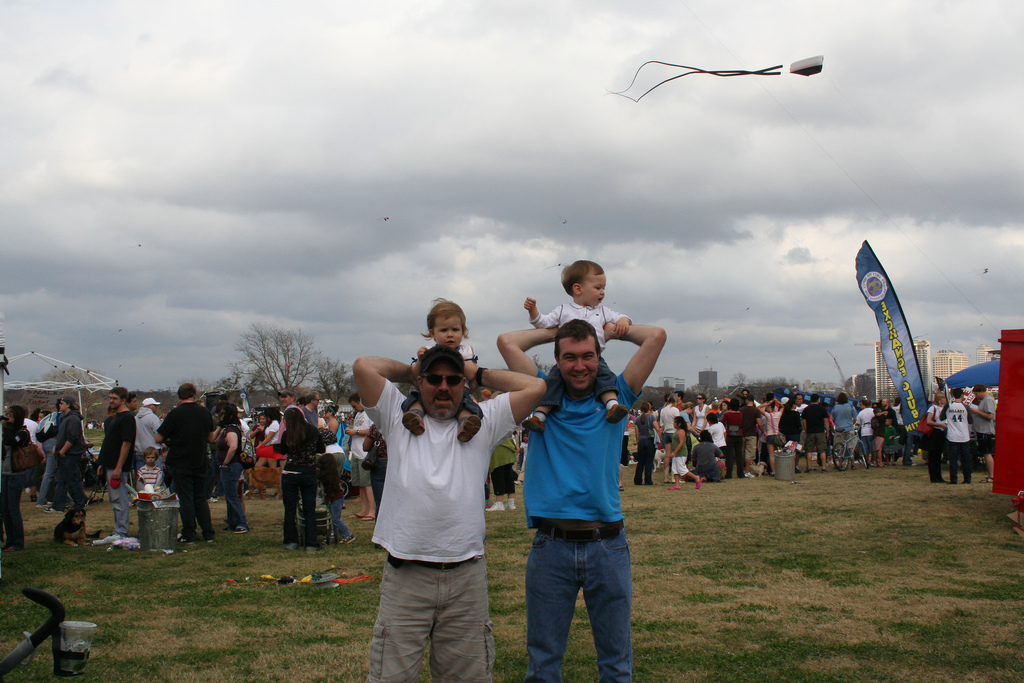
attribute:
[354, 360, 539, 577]
shirt — white